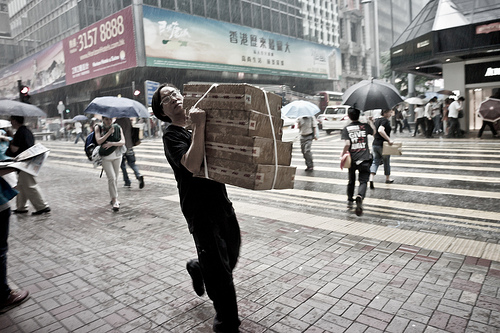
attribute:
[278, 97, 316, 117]
umbrella — white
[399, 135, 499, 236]
white lines — broad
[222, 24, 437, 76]
advertisement — large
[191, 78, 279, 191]
string — white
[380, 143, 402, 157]
boxes — brown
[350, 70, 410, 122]
umbrella — large, open, black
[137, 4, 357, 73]
sign — large, white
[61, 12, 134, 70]
large banner — advertisement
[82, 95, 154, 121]
umbrella — black, open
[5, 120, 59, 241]
person — holding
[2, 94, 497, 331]
street — wey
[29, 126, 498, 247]
road — wey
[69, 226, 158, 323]
sidewalk — brick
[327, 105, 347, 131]
car — white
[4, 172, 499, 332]
brick sidewalk — paved